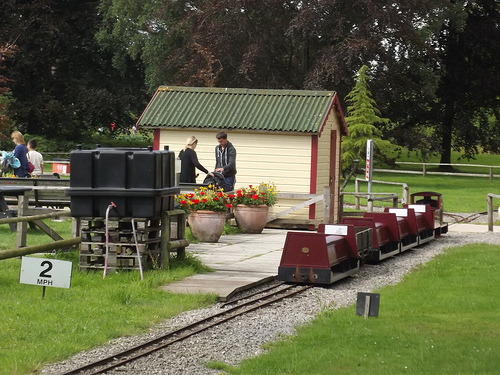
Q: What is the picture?
A: Miniature train.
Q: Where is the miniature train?
A: On tracks.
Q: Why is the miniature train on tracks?
A: To drive.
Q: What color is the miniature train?
A: Red.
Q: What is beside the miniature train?
A: Building.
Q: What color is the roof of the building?
A: Green.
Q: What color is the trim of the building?
A: Red.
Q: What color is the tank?
A: Black.